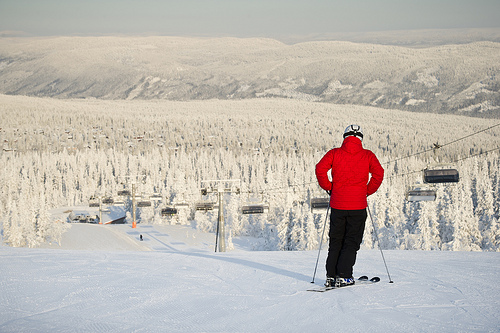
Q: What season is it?
A: Winter.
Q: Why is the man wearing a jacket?
A: It is cold.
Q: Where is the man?
A: Hill.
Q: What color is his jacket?
A: Red.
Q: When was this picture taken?
A: During the day.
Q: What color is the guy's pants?
A: Black.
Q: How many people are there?
A: 1.